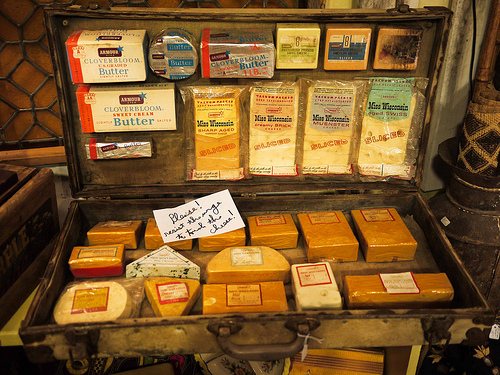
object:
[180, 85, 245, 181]
cheese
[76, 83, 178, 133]
butter stick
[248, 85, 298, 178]
swiss cheese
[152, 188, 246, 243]
note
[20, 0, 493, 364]
luggage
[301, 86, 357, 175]
muenster cheese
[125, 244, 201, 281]
cheese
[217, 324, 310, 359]
handle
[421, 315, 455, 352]
buckle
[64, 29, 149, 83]
butter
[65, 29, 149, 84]
box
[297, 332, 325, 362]
tag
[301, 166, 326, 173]
sticker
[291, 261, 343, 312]
cheese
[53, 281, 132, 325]
cheese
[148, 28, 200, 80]
butter block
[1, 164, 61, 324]
box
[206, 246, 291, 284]
cheese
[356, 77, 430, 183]
bag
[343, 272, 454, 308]
cheese brick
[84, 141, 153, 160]
package